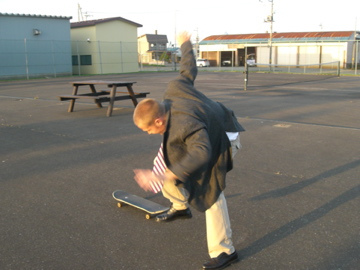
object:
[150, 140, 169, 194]
tie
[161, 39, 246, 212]
suit coat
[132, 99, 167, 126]
hair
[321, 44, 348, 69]
garage door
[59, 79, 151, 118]
table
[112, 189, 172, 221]
skateboard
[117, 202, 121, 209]
wheel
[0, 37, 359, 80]
fence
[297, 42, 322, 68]
garage door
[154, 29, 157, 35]
chimney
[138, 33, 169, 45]
roof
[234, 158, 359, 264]
shadow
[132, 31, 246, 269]
young boy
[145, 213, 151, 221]
wheel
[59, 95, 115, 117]
picnic bench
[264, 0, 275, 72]
utility pole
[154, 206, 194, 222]
shoe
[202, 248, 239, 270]
shoe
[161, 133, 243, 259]
pants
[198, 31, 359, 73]
building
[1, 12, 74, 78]
building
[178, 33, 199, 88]
arm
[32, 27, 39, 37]
light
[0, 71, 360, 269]
ground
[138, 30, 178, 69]
building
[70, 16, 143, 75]
building